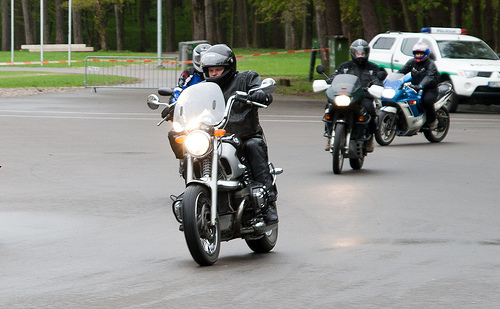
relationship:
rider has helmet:
[393, 30, 447, 147] [408, 34, 437, 58]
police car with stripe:
[364, 25, 499, 103] [372, 58, 409, 74]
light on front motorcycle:
[182, 130, 214, 156] [141, 80, 278, 263]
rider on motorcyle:
[205, 41, 299, 112] [148, 153, 298, 238]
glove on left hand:
[244, 89, 275, 106] [239, 80, 268, 103]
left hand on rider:
[239, 80, 268, 103] [161, 38, 279, 226]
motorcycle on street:
[141, 80, 278, 263] [2, 62, 497, 306]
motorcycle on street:
[360, 37, 474, 155] [16, 63, 484, 295]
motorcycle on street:
[310, 64, 375, 171] [16, 63, 484, 295]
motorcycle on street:
[141, 80, 278, 263] [16, 63, 484, 295]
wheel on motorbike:
[178, 181, 227, 263] [149, 66, 298, 259]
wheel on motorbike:
[236, 180, 280, 254] [149, 66, 298, 259]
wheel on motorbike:
[324, 119, 348, 170] [304, 70, 399, 186]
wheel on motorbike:
[374, 104, 401, 150] [370, 65, 459, 150]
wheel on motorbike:
[421, 97, 452, 143] [370, 65, 459, 150]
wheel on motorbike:
[239, 193, 283, 253] [144, 77, 282, 267]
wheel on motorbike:
[178, 185, 213, 267] [164, 44, 301, 273]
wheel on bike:
[344, 128, 376, 170] [307, 50, 383, 177]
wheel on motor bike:
[370, 102, 402, 148] [376, 65, 473, 137]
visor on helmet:
[199, 51, 227, 70] [201, 46, 238, 78]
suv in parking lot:
[365, 25, 497, 115] [5, 99, 497, 307]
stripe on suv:
[359, 60, 464, 82] [344, 15, 498, 125]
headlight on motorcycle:
[182, 130, 211, 154] [147, 85, 283, 265]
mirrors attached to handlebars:
[146, 81, 283, 111] [146, 84, 283, 129]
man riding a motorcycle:
[162, 42, 278, 221] [147, 85, 283, 265]